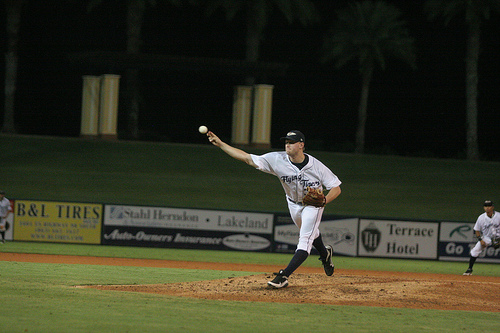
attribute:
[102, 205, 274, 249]
sign — black, white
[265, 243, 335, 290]
cleats — black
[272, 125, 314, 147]
hat — black, white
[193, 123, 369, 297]
player — baseball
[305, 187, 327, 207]
glove — brown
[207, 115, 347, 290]
pitcher — baseball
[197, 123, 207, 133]
baseball — white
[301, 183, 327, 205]
glove — brown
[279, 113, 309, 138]
cap — black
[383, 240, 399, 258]
capital letter — black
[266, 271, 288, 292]
shoe — black, white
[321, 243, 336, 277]
shoe — black, white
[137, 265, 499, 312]
pitcher's mound — dirt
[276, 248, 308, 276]
sock — black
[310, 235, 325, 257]
sock — black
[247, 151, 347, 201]
shirt — black, white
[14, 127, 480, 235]
hill — green, grassy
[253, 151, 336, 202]
shirt — white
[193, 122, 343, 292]
pitcher — baseball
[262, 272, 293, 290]
cleat — black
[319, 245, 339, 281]
cleat — black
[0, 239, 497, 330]
field — baseball